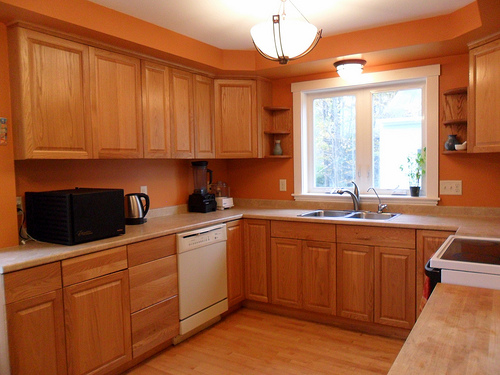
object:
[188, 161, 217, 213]
blender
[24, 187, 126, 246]
microwave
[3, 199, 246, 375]
counter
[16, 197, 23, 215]
outlet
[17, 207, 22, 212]
plugs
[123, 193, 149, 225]
coffeepot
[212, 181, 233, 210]
processor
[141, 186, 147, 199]
outlet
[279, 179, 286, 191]
outlet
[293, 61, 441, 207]
window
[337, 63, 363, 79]
light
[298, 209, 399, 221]
sink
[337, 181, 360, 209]
faucet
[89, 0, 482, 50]
ceiling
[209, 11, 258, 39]
shade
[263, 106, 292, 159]
shelf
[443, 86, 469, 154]
shelf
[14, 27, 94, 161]
cabinets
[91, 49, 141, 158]
doors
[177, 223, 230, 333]
dishwasher